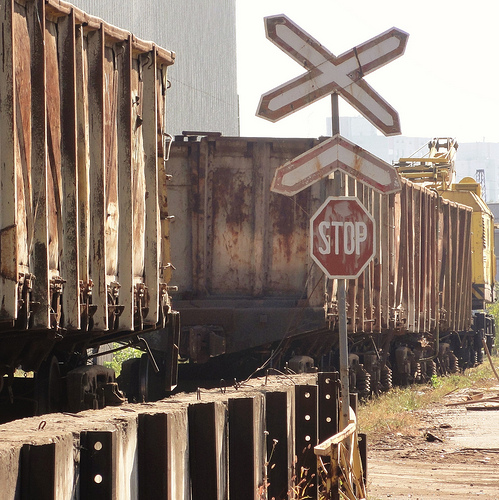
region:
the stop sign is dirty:
[310, 195, 376, 279]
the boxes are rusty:
[1, 3, 474, 333]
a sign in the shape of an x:
[256, 16, 407, 137]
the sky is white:
[239, 1, 494, 140]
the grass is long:
[346, 355, 494, 444]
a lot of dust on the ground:
[362, 380, 496, 496]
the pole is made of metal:
[337, 278, 346, 428]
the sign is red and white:
[308, 197, 372, 279]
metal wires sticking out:
[33, 368, 296, 430]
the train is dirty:
[0, 0, 480, 397]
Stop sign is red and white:
[301, 188, 388, 307]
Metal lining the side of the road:
[32, 399, 394, 485]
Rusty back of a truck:
[180, 151, 449, 367]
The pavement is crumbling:
[390, 412, 494, 491]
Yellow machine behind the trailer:
[409, 126, 485, 255]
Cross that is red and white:
[246, 1, 417, 135]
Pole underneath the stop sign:
[322, 280, 378, 459]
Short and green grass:
[374, 402, 401, 431]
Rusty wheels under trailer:
[349, 340, 432, 398]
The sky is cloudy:
[417, 17, 487, 87]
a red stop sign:
[304, 192, 382, 281]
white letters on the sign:
[312, 215, 371, 259]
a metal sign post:
[336, 276, 357, 429]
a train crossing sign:
[251, 2, 413, 141]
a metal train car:
[157, 117, 489, 392]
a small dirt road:
[358, 448, 496, 498]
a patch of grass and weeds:
[353, 355, 496, 439]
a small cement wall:
[0, 366, 331, 498]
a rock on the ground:
[423, 427, 446, 446]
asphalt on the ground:
[419, 392, 498, 455]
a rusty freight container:
[168, 144, 474, 340]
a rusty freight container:
[5, 3, 176, 327]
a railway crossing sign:
[254, 4, 403, 475]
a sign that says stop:
[311, 196, 382, 285]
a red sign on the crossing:
[302, 187, 375, 286]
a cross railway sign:
[264, 15, 425, 140]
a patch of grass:
[358, 364, 492, 432]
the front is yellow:
[410, 130, 497, 292]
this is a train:
[7, 1, 493, 477]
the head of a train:
[450, 168, 487, 304]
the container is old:
[84, 129, 275, 431]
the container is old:
[64, 156, 192, 345]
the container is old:
[129, 219, 181, 280]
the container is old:
[19, 32, 195, 288]